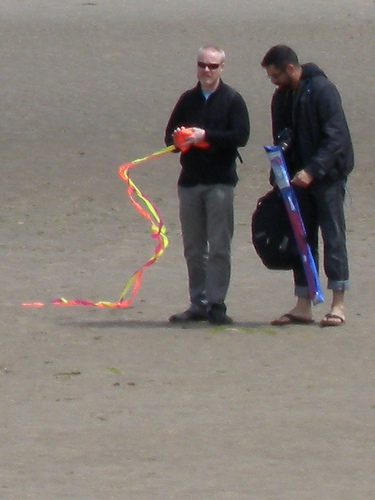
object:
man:
[250, 39, 355, 326]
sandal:
[269, 310, 317, 329]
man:
[163, 43, 252, 327]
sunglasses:
[195, 64, 222, 72]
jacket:
[269, 62, 354, 188]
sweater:
[164, 78, 251, 191]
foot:
[318, 304, 346, 332]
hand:
[285, 171, 314, 191]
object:
[257, 141, 329, 306]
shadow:
[63, 307, 300, 329]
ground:
[2, 2, 372, 497]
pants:
[283, 168, 349, 298]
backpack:
[248, 179, 323, 272]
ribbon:
[19, 141, 182, 311]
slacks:
[177, 178, 235, 305]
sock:
[166, 301, 208, 324]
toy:
[171, 122, 209, 154]